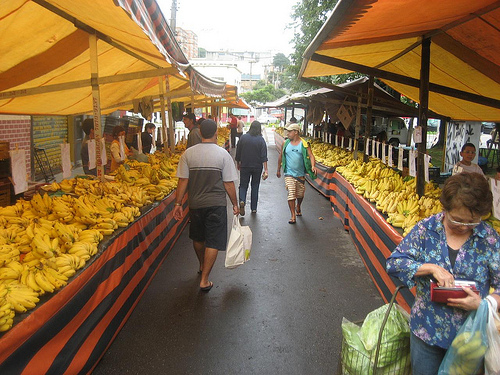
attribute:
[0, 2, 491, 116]
awnings — Orange, yellow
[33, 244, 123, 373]
tablecloth — orange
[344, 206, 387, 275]
cover — red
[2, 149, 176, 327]
bananas — yellow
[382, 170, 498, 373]
woman — looking at wallet, checking her wallet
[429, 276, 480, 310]
her wallet — opened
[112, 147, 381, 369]
cement — black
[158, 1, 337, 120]
in the distance — trees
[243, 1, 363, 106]
trees — tall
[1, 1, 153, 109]
canopy — yellow